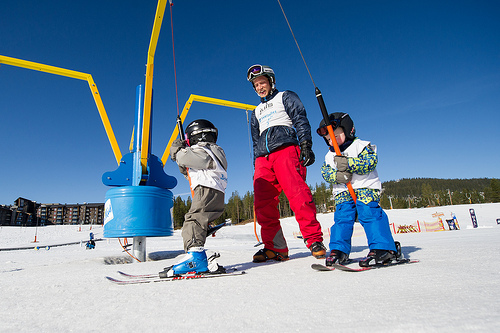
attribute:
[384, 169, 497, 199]
mountain — tree covered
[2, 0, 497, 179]
sky — blue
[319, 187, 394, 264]
pants — blue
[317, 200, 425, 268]
pants — blue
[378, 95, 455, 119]
cloud — white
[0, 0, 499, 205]
sky — blue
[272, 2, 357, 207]
pole — orange, black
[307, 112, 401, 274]
child — black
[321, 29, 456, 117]
sky — clear, blue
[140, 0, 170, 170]
pole — yellow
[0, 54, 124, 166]
pole — yellow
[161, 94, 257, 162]
pole — yellow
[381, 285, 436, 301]
snow — white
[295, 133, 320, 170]
glove — black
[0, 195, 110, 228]
hotel — brown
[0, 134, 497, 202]
cloud — white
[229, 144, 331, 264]
snow pants — pink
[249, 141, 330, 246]
pants — red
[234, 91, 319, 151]
jacket — dark blue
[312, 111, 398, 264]
small child — skiing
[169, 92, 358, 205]
handles — black, orange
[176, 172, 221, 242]
pants — gray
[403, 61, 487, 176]
clouds — white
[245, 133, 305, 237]
pants — red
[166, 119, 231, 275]
child — skiing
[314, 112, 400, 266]
child — skiing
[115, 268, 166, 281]
ski — small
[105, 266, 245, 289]
ski — small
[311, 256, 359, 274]
ski — small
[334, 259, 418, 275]
ski — small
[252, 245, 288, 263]
shoe — yellow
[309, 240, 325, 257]
shoe — yellow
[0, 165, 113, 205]
clouds — white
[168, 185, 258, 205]
clouds — white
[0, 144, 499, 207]
clouds — white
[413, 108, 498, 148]
clouds — white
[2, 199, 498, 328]
snow — white